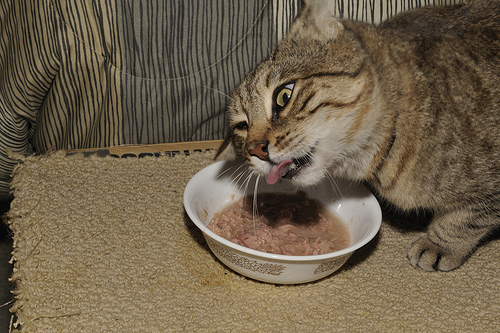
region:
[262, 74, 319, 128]
the right eye of a cat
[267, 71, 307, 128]
the right eye of a kitten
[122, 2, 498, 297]
a cat enjoying a meal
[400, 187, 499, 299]
the right paw of a kitten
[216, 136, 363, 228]
nose, mouth and whiskers of a cat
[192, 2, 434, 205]
a cat's face while eating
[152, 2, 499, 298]
a cat distracted by it's meal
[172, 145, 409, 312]
a white dish of catfood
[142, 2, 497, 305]
a kitten during mealtime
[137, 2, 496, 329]
a cat during mealtime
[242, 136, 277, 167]
the nose of a cat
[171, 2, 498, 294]
a cat eating catfood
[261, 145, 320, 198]
the tongue of a cat eating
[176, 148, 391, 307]
a white bowl with catfood in it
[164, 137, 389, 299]
a white bowl containing catfood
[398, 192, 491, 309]
the right front paw of a cat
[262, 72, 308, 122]
the left eye of a cat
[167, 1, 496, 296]
a cat trying to eat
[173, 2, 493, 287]
a cat distracted while eating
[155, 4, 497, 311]
a cat enjoying food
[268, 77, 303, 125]
eye of a cat eating food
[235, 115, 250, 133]
eye of a cat eating food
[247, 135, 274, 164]
nose of a cat eating food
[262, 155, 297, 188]
tongue of a cat eating food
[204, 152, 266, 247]
whiskers of a cat eating food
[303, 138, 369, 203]
whiskers of a cat eating food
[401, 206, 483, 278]
paw of a cat eating food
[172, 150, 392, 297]
white bowl full of cat food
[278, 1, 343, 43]
ear of a cat eating food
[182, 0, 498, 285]
cat eating food out of a bowl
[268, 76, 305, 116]
eye of a cat eating some food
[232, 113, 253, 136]
eye of a cat eating some food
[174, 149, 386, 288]
white bowl filled with cat food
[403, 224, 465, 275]
paw of a cat eating some food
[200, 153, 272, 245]
whiskers of a cat eating some food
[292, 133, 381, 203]
whiskers of a cat eating some food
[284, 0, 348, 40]
ear of a cat eating some food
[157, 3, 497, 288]
eat eating food out of a bowl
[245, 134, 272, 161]
nose of a cat eating some food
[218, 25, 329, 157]
cat has brown ears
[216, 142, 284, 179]
cat has brown nose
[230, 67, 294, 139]
cat has hazel eyes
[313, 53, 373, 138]
brown stripes on face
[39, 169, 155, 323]
brown rug under cat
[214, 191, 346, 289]
pink food in bowl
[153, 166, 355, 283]
small bowl is white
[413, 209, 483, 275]
cat has tan paws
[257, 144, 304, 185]
cat has pink tongue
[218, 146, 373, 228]
cat has thin whiskers